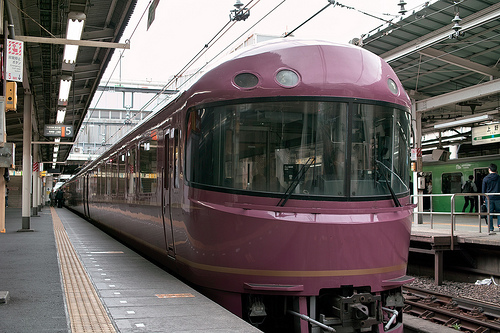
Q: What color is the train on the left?
A: Purple.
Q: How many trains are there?
A: Two.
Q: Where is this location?
A: Train stop.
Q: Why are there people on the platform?
A: Unloading and reloading.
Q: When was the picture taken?
A: Daytime.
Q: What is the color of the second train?
A: Green.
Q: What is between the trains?
A: A platform.